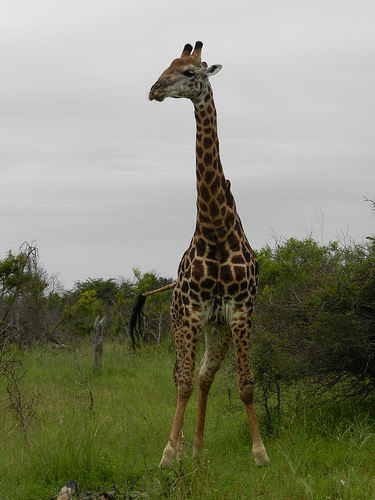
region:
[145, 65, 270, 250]
the giraffe's neck is long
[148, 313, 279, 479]
the giraffe has four legs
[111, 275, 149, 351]
the giraffe's tail is black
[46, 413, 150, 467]
the grass is green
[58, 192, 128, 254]
the sky is gray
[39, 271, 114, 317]
the bushes is green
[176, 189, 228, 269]
the fur is brown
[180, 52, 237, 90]
the ear is white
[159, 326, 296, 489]
the legs are tall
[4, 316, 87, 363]
the branches are bare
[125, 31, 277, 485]
Giraffe stand in the meadow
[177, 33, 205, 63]
Giraffe has two horns on head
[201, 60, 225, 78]
Ears of giraffe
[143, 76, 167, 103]
Muzzle of giraffe is close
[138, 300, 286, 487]
Front legs of giraffe are strong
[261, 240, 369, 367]
Green bushes in the meadow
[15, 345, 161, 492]
Green grass is hight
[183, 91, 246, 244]
Long neck of giraffe with brown spots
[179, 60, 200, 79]
Eye of giraffe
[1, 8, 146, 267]
Sky is cloudy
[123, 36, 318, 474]
a large giraffe standing in the brush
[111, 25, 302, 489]
a tall spotted giraffe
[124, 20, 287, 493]
a long necked animal standing amid vegetation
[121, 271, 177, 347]
tail of the giraffe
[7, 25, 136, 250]
the sky is overcast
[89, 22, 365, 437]
a giraffe standing next to some bushes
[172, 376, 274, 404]
the knees of the giraffe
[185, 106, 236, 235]
the neck of the giraffe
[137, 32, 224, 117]
the head of the giraffe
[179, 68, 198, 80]
the eye of the giraffe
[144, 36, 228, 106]
a giraffe's head turned to its right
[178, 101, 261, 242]
giraffe's long neck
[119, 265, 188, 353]
giraffe tail swinging to the side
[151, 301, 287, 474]
long giraffe legs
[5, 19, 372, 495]
a giraffe standing alone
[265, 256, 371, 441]
thick green bushes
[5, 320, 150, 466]
wild growing green grass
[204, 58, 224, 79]
a giraffe's ear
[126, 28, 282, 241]
a giraffe's head and neck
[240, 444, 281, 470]
a giraffe's hoof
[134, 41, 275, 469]
giraffe in a field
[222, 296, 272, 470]
front left leg of giraffe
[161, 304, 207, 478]
front right leg of giraffe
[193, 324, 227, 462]
back left leg of giraffe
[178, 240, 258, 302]
chest of giraffe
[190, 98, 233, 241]
neck of the giraffe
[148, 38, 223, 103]
head of the giraffe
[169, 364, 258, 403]
knees of the giraffe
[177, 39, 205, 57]
horns of the giraffe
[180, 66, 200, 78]
left eye of the giraffe